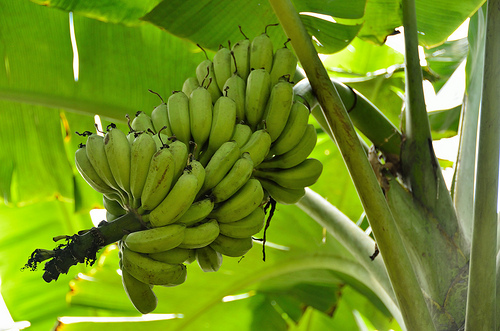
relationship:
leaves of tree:
[57, 3, 467, 137] [267, 0, 497, 329]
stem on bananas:
[28, 218, 139, 280] [68, 25, 322, 320]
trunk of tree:
[386, 150, 470, 330] [267, 0, 497, 329]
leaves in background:
[57, 3, 467, 137] [2, 0, 499, 230]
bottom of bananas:
[122, 111, 320, 295] [68, 25, 322, 320]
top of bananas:
[74, 31, 273, 184] [68, 25, 322, 320]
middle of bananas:
[149, 71, 278, 217] [68, 25, 322, 320]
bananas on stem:
[68, 25, 322, 320] [28, 218, 139, 280]